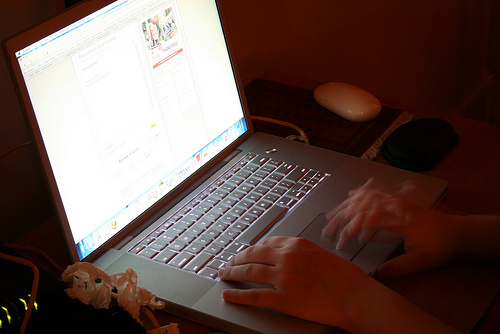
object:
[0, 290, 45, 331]
lights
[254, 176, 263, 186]
key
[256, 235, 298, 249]
finger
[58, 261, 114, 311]
tissue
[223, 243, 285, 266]
middle finger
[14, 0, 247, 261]
computer screen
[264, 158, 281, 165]
keys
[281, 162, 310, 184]
keys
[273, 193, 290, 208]
keys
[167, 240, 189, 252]
silver key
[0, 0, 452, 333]
computer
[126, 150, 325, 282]
keyboard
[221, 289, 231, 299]
fingernail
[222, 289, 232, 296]
person's fingernail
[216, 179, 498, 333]
person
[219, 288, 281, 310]
pinky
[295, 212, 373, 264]
mouse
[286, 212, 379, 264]
mouse pad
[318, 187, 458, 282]
hand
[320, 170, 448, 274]
motion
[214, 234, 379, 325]
hands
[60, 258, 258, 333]
side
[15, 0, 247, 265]
website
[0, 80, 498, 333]
table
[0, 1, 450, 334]
lit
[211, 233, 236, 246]
key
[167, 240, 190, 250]
key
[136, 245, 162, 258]
key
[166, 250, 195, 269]
key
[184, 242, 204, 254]
key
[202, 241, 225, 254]
key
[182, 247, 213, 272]
key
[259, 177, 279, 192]
key